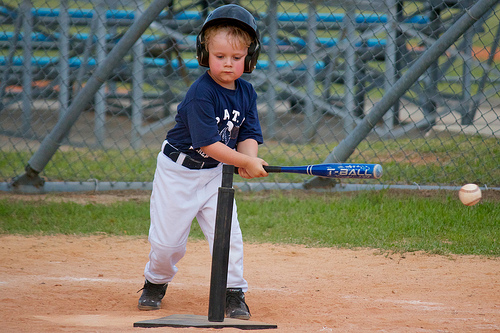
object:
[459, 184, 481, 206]
baseball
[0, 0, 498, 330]
air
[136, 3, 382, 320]
boy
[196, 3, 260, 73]
helmet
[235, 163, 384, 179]
bat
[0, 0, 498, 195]
fence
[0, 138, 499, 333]
field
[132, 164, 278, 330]
stand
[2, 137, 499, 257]
grass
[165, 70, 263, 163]
shirt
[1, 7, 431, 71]
bleachers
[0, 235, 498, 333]
dirt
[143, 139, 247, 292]
pants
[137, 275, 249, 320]
cleats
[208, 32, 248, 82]
pink cheeks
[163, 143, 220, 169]
belt